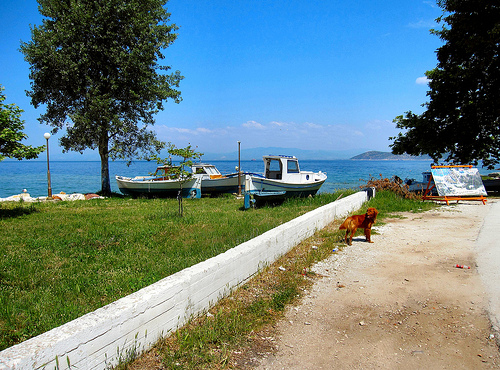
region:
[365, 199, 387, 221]
head of a dog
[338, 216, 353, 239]
tail of a dog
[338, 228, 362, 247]
feet of a dog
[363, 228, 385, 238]
feet of a dog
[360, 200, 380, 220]
a head of a dog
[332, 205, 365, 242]
a body of a dog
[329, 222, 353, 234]
a tail of a dog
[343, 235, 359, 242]
a leg of a dog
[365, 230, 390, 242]
a leg of a dog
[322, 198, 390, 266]
dog on a field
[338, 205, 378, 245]
red retriever on side of road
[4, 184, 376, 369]
low white wall separating grass from road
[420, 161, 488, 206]
large sign on orange support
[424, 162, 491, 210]
large sign in road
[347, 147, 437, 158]
mountain across water in background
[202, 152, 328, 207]
white boat with blue stripe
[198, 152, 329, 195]
boat out of water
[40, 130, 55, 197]
lamp post on side of grass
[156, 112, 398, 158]
low clouds in blue sky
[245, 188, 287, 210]
small brown dingy on ground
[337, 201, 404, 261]
a do is beside the wall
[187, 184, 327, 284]
the wall is made of conrete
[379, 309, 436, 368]
the floor is coverd of sand and dirt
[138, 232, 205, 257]
grasse are beside th wall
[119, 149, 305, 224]
boats re parked next to the ocean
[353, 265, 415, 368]
the floor is brown in coloe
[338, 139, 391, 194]
water is blue incolor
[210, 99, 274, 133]
sky is cob=verd of white clouds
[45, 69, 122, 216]
a tree is next to the ocean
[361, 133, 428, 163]
hills are at the background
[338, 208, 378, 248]
Brown dog with long tail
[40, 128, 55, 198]
Light pole with white globe fixture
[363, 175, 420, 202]
Dead tree branch with brown leaves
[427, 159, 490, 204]
Large art display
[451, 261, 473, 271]
Plastic bottle with red label and cover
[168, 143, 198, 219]
Young tree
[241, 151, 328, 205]
White and blue boat parked on the lawn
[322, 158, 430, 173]
Large body of water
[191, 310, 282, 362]
Weeds and grass growing at edge of gravel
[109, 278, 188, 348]
White stone wall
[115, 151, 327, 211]
boats in the grass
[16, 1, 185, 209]
tree beside the boat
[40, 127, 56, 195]
street light behind the tree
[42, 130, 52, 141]
light bulb is white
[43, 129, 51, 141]
light bulb is circular shaped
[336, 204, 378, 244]
dog standing beside dirt road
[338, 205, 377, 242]
the dog is brown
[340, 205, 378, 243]
dog is looking back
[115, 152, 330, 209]
the boats are empty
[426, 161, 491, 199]
sign in the road